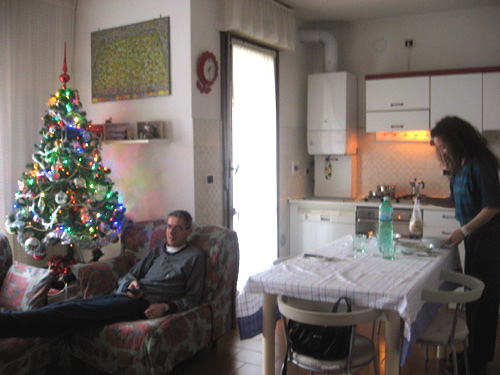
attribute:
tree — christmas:
[22, 66, 118, 229]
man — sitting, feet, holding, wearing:
[128, 238, 213, 305]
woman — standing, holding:
[411, 118, 495, 310]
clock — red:
[189, 49, 230, 91]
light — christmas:
[377, 120, 446, 170]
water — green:
[352, 188, 400, 275]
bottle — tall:
[368, 161, 417, 272]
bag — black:
[43, 253, 75, 301]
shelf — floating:
[100, 108, 168, 162]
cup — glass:
[384, 203, 437, 256]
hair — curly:
[437, 144, 477, 188]